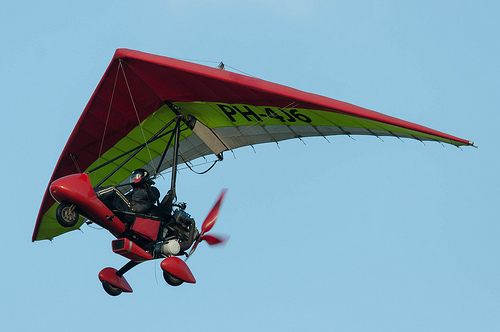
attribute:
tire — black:
[161, 266, 193, 290]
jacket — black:
[121, 170, 148, 209]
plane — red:
[66, 51, 351, 202]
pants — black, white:
[93, 183, 130, 209]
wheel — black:
[52, 197, 90, 231]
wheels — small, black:
[101, 273, 186, 298]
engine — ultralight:
[164, 203, 197, 254]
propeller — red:
[189, 182, 229, 266]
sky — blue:
[1, 5, 491, 330]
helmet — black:
[119, 166, 156, 186]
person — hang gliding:
[71, 114, 208, 244]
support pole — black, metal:
[166, 122, 183, 206]